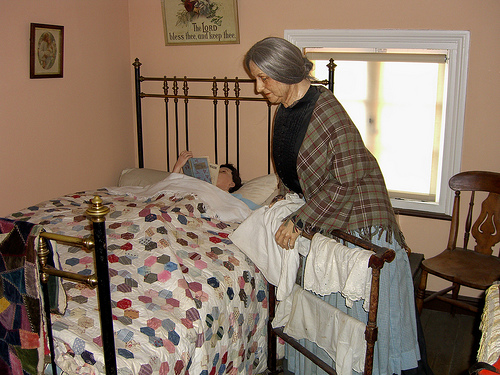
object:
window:
[286, 24, 472, 218]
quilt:
[0, 171, 272, 373]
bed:
[0, 56, 336, 371]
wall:
[0, 0, 137, 217]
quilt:
[0, 217, 68, 373]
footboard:
[1, 194, 118, 374]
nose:
[254, 76, 264, 95]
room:
[3, 0, 498, 373]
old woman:
[244, 34, 423, 374]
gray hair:
[241, 34, 312, 87]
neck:
[268, 87, 314, 104]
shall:
[282, 82, 409, 244]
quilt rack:
[270, 226, 385, 372]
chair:
[412, 168, 498, 369]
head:
[239, 33, 314, 106]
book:
[179, 156, 219, 185]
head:
[202, 145, 252, 202]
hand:
[172, 147, 194, 167]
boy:
[166, 144, 244, 195]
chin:
[268, 96, 278, 103]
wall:
[128, 1, 500, 315]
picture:
[154, 4, 244, 51]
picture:
[29, 19, 65, 81]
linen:
[226, 191, 308, 308]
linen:
[299, 231, 379, 309]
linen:
[268, 285, 373, 368]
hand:
[273, 220, 307, 250]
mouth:
[264, 89, 274, 98]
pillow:
[226, 172, 281, 205]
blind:
[304, 46, 448, 204]